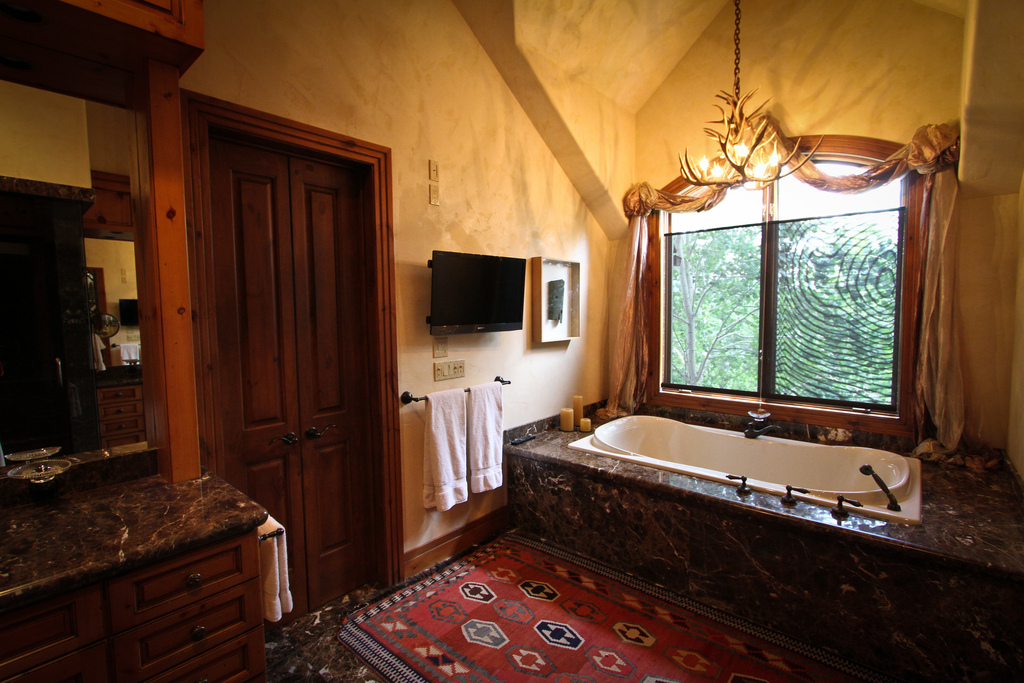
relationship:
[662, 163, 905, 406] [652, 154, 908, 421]
sunlight through window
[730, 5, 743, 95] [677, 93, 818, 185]
chain suspending chandelier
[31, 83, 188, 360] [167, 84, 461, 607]
mirror on other side of door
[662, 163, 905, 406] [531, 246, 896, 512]
sunlight coming through window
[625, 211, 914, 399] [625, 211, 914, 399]
sunlight coming through window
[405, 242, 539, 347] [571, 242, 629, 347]
television by artwork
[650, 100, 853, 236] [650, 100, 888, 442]
antlers are above window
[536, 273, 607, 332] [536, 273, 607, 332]
item in shadow box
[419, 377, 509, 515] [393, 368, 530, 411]
towels hanging from a towel rod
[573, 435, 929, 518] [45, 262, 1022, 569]
bathtub mounted inside a counter that fills end of room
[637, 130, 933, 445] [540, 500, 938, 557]
window with arched frame and elaborate window treatment on top by tub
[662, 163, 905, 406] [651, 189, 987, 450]
sunlight coming in through window